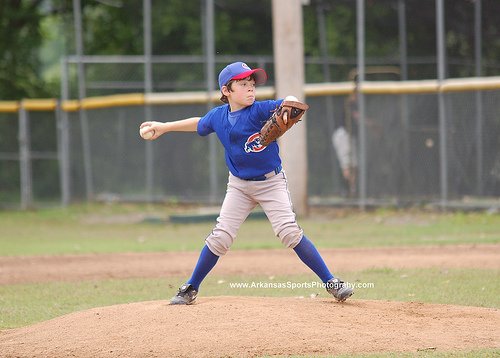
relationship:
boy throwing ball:
[138, 60, 353, 309] [138, 125, 154, 139]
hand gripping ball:
[138, 120, 162, 141] [138, 125, 154, 139]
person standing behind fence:
[330, 121, 358, 197] [0, 2, 499, 209]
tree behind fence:
[1, 2, 99, 197] [0, 2, 499, 209]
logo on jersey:
[242, 133, 265, 152] [199, 99, 282, 178]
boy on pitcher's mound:
[138, 60, 353, 309] [1, 295, 499, 352]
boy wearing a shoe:
[138, 60, 353, 309] [167, 282, 197, 305]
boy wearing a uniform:
[138, 60, 353, 309] [185, 101, 332, 286]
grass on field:
[0, 270, 500, 329] [1, 209, 498, 357]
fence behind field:
[0, 2, 499, 209] [1, 209, 498, 357]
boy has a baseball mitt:
[138, 60, 353, 309] [258, 99, 310, 144]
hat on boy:
[216, 62, 267, 88] [138, 60, 353, 309]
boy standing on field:
[138, 60, 353, 309] [1, 209, 498, 357]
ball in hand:
[138, 125, 154, 139] [138, 120, 162, 141]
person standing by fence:
[330, 121, 358, 197] [0, 2, 499, 209]